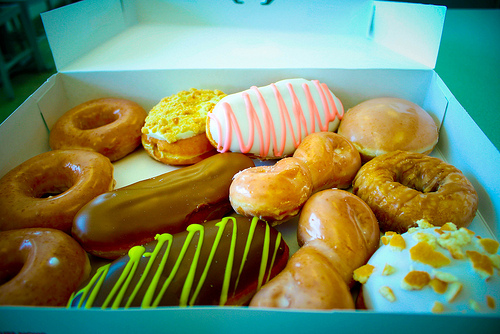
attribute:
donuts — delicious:
[35, 91, 494, 313]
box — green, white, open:
[1, 4, 500, 334]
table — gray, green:
[455, 13, 500, 91]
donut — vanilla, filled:
[222, 78, 341, 140]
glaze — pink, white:
[222, 98, 316, 135]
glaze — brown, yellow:
[105, 244, 244, 309]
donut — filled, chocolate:
[101, 240, 275, 303]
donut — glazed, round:
[55, 99, 141, 151]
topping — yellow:
[400, 232, 476, 286]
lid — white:
[47, 2, 445, 69]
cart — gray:
[1, 0, 40, 87]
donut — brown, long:
[80, 155, 231, 236]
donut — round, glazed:
[4, 150, 106, 215]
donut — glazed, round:
[1, 225, 82, 304]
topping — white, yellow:
[161, 98, 206, 127]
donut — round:
[144, 89, 210, 161]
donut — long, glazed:
[285, 193, 369, 307]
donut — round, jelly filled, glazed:
[345, 97, 440, 152]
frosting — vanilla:
[236, 98, 249, 129]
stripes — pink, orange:
[249, 92, 273, 148]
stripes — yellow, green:
[157, 237, 208, 289]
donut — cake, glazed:
[362, 154, 478, 223]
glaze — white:
[150, 132, 166, 141]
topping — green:
[189, 226, 239, 249]